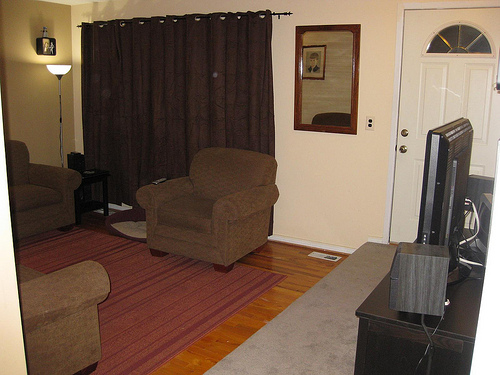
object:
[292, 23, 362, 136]
mirror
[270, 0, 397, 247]
wall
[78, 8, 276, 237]
curtains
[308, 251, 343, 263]
vent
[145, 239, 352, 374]
floor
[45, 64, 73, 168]
lamp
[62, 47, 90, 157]
corner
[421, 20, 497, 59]
window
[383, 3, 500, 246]
door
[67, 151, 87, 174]
speaker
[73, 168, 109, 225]
stand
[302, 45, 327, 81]
picture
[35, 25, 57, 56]
oleo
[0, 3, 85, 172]
wall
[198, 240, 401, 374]
carpet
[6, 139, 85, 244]
chairs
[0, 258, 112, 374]
furniture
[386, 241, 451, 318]
speaker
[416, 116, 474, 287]
television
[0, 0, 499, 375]
living room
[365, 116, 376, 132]
switch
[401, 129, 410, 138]
deadbolt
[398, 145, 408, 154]
doorknob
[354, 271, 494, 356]
countertop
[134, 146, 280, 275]
chair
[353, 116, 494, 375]
entertainment center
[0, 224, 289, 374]
carpet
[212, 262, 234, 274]
legs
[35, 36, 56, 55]
box